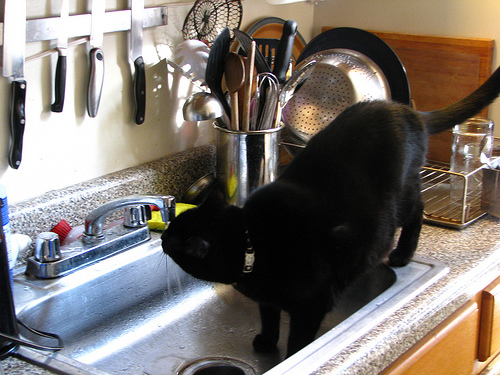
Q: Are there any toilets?
A: No, there are no toilets.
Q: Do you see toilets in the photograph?
A: No, there are no toilets.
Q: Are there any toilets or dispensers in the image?
A: No, there are no toilets or dispensers.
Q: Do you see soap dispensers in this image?
A: No, there are no soap dispensers.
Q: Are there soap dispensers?
A: No, there are no soap dispensers.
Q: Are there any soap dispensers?
A: No, there are no soap dispensers.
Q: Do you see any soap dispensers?
A: No, there are no soap dispensers.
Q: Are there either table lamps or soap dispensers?
A: No, there are no soap dispensers or table lamps.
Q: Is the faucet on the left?
A: Yes, the faucet is on the left of the image.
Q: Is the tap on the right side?
A: No, the tap is on the left of the image.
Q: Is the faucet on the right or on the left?
A: The faucet is on the left of the image.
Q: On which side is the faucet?
A: The faucet is on the left of the image.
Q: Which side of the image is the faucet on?
A: The faucet is on the left of the image.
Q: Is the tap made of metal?
A: Yes, the tap is made of metal.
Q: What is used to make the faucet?
A: The faucet is made of metal.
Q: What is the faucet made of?
A: The faucet is made of metal.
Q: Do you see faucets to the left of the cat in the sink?
A: Yes, there is a faucet to the left of the cat.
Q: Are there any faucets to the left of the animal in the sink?
A: Yes, there is a faucet to the left of the cat.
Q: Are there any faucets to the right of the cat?
A: No, the faucet is to the left of the cat.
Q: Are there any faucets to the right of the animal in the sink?
A: No, the faucet is to the left of the cat.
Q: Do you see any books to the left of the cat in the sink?
A: No, there is a faucet to the left of the cat.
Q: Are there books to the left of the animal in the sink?
A: No, there is a faucet to the left of the cat.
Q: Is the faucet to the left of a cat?
A: Yes, the faucet is to the left of a cat.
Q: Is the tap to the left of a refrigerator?
A: No, the tap is to the left of a cat.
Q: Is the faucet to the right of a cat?
A: No, the faucet is to the left of a cat.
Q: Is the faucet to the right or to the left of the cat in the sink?
A: The faucet is to the left of the cat.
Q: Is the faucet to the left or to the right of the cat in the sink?
A: The faucet is to the left of the cat.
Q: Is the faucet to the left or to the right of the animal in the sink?
A: The faucet is to the left of the cat.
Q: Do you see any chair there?
A: No, there are no chairs.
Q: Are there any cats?
A: Yes, there is a cat.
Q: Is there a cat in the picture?
A: Yes, there is a cat.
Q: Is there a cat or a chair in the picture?
A: Yes, there is a cat.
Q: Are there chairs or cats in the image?
A: Yes, there is a cat.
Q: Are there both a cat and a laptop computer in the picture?
A: No, there is a cat but no laptops.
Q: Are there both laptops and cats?
A: No, there is a cat but no laptops.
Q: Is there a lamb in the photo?
A: No, there are no lambs.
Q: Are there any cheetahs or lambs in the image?
A: No, there are no lambs or cheetahs.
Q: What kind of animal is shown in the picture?
A: The animal is a cat.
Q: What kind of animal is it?
A: The animal is a cat.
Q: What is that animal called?
A: This is a cat.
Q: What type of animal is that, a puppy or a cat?
A: This is a cat.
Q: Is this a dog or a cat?
A: This is a cat.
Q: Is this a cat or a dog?
A: This is a cat.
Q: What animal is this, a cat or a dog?
A: This is a cat.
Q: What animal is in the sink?
A: The animal is a cat.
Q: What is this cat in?
A: The cat is in the sink.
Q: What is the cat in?
A: The cat is in the sink.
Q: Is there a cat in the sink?
A: Yes, there is a cat in the sink.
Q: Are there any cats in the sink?
A: Yes, there is a cat in the sink.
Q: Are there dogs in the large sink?
A: No, there is a cat in the sink.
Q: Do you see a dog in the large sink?
A: No, there is a cat in the sink.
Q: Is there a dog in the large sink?
A: No, there is a cat in the sink.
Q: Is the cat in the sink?
A: Yes, the cat is in the sink.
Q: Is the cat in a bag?
A: No, the cat is in the sink.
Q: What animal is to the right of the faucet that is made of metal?
A: The animal is a cat.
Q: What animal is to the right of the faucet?
A: The animal is a cat.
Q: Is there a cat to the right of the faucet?
A: Yes, there is a cat to the right of the faucet.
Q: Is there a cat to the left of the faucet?
A: No, the cat is to the right of the faucet.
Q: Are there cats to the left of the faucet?
A: No, the cat is to the right of the faucet.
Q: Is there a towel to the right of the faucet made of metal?
A: No, there is a cat to the right of the faucet.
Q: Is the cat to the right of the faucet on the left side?
A: Yes, the cat is to the right of the tap.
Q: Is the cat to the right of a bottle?
A: No, the cat is to the right of the tap.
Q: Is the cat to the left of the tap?
A: No, the cat is to the right of the tap.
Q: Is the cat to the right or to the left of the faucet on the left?
A: The cat is to the right of the faucet.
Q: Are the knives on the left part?
A: Yes, the knives are on the left of the image.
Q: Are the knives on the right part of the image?
A: No, the knives are on the left of the image.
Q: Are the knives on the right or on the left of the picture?
A: The knives are on the left of the image.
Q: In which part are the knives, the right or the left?
A: The knives are on the left of the image.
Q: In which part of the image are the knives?
A: The knives are on the left of the image.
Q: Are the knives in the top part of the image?
A: Yes, the knives are in the top of the image.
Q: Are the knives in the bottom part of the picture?
A: No, the knives are in the top of the image.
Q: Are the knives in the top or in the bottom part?
A: The knives are in the top of the image.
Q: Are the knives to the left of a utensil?
A: Yes, the knives are to the left of a utensil.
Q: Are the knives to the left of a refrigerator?
A: No, the knives are to the left of a utensil.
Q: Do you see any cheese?
A: No, there is no cheese.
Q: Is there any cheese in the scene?
A: No, there is no cheese.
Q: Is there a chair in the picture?
A: No, there are no chairs.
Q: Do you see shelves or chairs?
A: No, there are no chairs or shelves.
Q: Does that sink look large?
A: Yes, the sink is large.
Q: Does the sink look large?
A: Yes, the sink is large.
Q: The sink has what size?
A: The sink is large.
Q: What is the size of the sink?
A: The sink is large.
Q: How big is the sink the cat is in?
A: The sink is large.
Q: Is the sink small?
A: No, the sink is large.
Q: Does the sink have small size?
A: No, the sink is large.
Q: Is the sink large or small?
A: The sink is large.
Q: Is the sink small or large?
A: The sink is large.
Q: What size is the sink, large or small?
A: The sink is large.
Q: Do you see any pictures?
A: No, there are no pictures.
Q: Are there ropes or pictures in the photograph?
A: No, there are no pictures or ropes.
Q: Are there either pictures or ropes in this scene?
A: No, there are no pictures or ropes.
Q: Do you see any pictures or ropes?
A: No, there are no pictures or ropes.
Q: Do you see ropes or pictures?
A: No, there are no pictures or ropes.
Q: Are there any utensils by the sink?
A: Yes, there is a utensil by the sink.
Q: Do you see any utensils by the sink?
A: Yes, there is a utensil by the sink.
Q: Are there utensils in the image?
A: Yes, there are utensils.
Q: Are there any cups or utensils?
A: Yes, there are utensils.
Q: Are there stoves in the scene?
A: No, there are no stoves.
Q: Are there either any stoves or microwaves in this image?
A: No, there are no stoves or microwaves.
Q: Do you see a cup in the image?
A: No, there are no cups.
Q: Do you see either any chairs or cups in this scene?
A: No, there are no cups or chairs.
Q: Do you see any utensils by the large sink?
A: Yes, there is a utensil by the sink.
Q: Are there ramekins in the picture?
A: No, there are no ramekins.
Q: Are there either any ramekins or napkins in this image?
A: No, there are no ramekins or napkins.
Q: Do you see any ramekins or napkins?
A: No, there are no ramekins or napkins.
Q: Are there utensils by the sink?
A: Yes, there is a utensil by the sink.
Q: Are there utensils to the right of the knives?
A: Yes, there is a utensil to the right of the knives.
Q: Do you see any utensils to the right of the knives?
A: Yes, there is a utensil to the right of the knives.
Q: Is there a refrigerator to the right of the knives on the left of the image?
A: No, there is a utensil to the right of the knives.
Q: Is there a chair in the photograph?
A: No, there are no chairs.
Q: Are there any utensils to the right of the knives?
A: Yes, there is a utensil to the right of the knives.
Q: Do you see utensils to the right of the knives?
A: Yes, there is a utensil to the right of the knives.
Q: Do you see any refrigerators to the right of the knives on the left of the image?
A: No, there is a utensil to the right of the knives.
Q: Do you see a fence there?
A: No, there are no fences.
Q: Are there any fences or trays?
A: No, there are no fences or trays.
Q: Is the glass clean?
A: Yes, the glass is clean.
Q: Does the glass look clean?
A: Yes, the glass is clean.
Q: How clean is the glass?
A: The glass is clean.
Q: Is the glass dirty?
A: No, the glass is clean.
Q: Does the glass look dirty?
A: No, the glass is clean.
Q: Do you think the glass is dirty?
A: No, the glass is clean.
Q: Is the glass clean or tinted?
A: The glass is clean.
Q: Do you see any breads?
A: No, there are no breads.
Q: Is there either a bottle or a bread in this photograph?
A: No, there are no breads or bottles.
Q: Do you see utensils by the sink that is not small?
A: Yes, there is a utensil by the sink.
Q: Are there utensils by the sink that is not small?
A: Yes, there is a utensil by the sink.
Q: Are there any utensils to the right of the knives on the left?
A: Yes, there is a utensil to the right of the knives.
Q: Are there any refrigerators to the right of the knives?
A: No, there is a utensil to the right of the knives.